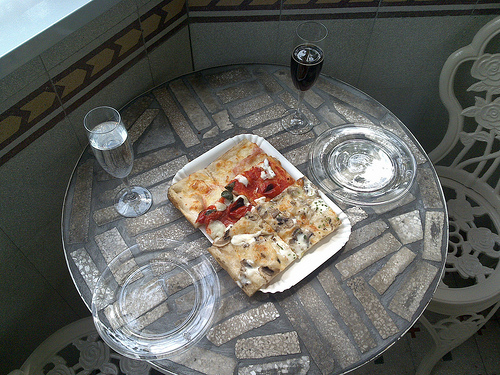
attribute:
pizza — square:
[168, 140, 341, 297]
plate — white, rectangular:
[172, 134, 351, 294]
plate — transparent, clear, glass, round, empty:
[308, 123, 417, 207]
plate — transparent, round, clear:
[92, 238, 220, 361]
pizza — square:
[208, 209, 296, 297]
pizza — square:
[254, 179, 341, 258]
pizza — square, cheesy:
[208, 143, 294, 205]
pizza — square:
[168, 169, 255, 240]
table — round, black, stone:
[63, 64, 449, 375]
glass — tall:
[86, 107, 153, 218]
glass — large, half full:
[282, 21, 328, 134]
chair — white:
[0, 316, 163, 374]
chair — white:
[421, 15, 498, 374]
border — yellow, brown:
[1, 1, 499, 166]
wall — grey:
[1, 0, 497, 373]